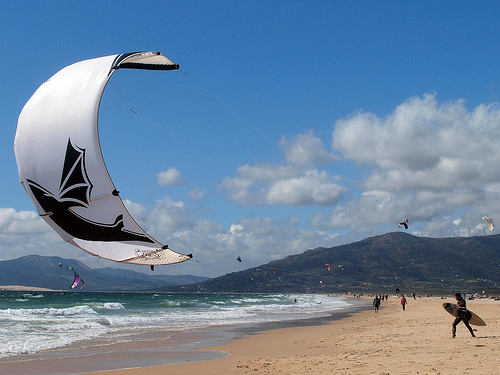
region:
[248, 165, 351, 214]
little fluffy cloud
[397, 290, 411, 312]
woman wears red shirt, black pants, walks along beach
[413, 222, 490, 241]
wind farm on a hill in the distance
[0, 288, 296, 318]
sea is green, & gorgeous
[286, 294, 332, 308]
people in the sea, near the shore, in the distance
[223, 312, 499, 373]
footprints all over the sand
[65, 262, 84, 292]
magenta+white+black windsail far in the back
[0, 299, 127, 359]
several tiny wavelets near the shoreline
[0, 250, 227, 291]
two blue green hills in the far distance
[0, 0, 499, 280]
blue sky, getting cloudier & greyer as the land rises to meet it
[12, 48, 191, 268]
Large white kite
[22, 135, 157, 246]
Image printed on the large white kite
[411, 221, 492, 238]
Windmills on the mountains in the background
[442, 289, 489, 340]
Person carrying a surfboard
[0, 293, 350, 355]
Waves crashing near the shore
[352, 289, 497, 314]
People in the background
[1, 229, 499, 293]
Mountains in the background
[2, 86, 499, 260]
Clouds in the sky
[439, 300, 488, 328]
Surfboard being held by the surfer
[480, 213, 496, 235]
The kite furthest to the right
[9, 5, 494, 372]
Beach scene on a partly cloudy day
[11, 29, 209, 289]
Black and white decorative kite in the air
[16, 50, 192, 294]
kite has a black dolphin on it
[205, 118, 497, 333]
mountains in the background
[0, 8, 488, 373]
Sky is partly cloudy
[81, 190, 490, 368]
Sand is light brown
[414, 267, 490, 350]
Man carrying a surfboard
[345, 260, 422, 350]
People walking on sand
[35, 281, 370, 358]
Waves coming inward to coastline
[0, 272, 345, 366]
ocean waves with white top-caps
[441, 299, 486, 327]
long pointed yellow surfboard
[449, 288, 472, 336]
person in black wetsuit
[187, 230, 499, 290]
mountain range in distance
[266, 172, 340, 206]
white fluffy cloud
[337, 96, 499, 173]
white fluffy cloud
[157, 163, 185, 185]
white fluffy cloud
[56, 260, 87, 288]
pink and black large flying kite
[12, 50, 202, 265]
black and white large flying kite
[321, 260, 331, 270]
red and white large kite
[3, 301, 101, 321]
white crested wave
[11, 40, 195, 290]
a billowing sail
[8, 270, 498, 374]
a populated beach scene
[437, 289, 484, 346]
a man with a surfboard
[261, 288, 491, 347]
a man headed to the water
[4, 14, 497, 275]
a sky with clouds over land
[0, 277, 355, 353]
small waves breaking at shore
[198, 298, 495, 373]
a wide expanse of beach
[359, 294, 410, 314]
two people walking in the sand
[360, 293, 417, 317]
a couple not close to each other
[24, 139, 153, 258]
a smiling fish with fins